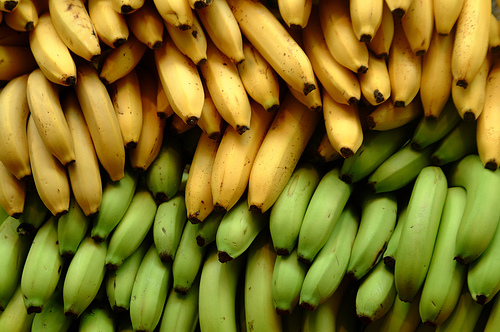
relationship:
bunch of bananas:
[0, 0, 498, 330] [1, 0, 498, 330]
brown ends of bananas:
[173, 79, 395, 159] [1, 0, 498, 330]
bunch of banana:
[0, 0, 498, 329] [395, 163, 448, 300]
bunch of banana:
[0, 0, 498, 329] [346, 194, 397, 283]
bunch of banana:
[0, 0, 498, 329] [298, 168, 352, 264]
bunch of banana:
[0, 0, 498, 329] [353, 260, 397, 322]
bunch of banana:
[0, 0, 498, 329] [217, 195, 261, 262]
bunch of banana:
[0, 0, 498, 329] [152, 197, 182, 262]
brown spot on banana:
[63, 2, 97, 44] [44, 0, 104, 65]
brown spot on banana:
[188, 28, 202, 41] [161, 19, 207, 64]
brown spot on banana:
[164, 10, 180, 19] [152, 0, 193, 30]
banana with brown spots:
[231, 1, 316, 96] [228, 0, 310, 82]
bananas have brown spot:
[1, 0, 498, 330] [464, 24, 476, 30]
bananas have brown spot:
[1, 0, 498, 330] [281, 50, 287, 58]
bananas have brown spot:
[1, 0, 498, 330] [401, 50, 405, 58]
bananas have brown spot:
[1, 0, 498, 330] [418, 35, 425, 44]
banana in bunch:
[0, 210, 56, 313] [0, 207, 197, 326]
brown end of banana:
[450, 72, 472, 93] [450, 0, 481, 90]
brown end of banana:
[302, 81, 316, 97] [239, 8, 319, 97]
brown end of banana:
[450, 251, 469, 271] [443, 169, 483, 267]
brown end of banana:
[20, 299, 41, 317] [20, 228, 59, 319]